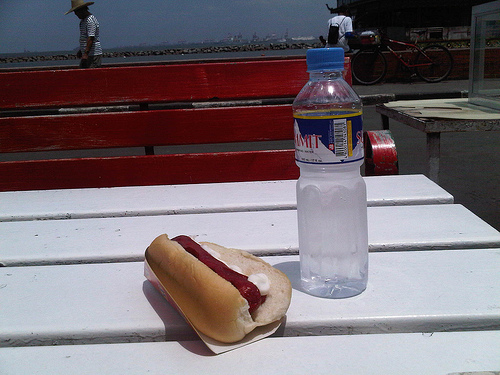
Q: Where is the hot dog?
A: Bun.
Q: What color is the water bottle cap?
A: Blue.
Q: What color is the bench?
A: Red.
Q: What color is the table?
A: White.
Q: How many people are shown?
A: Two.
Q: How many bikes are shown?
A: One.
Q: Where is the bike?
A: At the sidewalk.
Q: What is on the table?
A: Food and water.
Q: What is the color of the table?
A: White.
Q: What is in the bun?
A: A hot dog.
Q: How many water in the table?
A: One.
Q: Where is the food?
A: On the table.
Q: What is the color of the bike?
A: Red.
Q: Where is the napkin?
A: Under the hotdog.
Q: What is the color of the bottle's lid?
A: Blue.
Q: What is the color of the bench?
A: Red.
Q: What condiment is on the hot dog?
A: Mayo.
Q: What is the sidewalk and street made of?
A: Cement and asphalt.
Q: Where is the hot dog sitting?
A: Table.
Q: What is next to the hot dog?
A: Water bottle.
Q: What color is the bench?
A: Red.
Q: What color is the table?
A: White.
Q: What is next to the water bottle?
A: Hot dog.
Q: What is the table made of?
A: Gray wooden slats.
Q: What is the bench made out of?
A: Wood.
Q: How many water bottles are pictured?
A: One.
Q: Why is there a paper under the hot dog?
A: Protection.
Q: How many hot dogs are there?
A: One.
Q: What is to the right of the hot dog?
A: A bottle.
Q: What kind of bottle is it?
A: A water bottle.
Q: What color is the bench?
A: Red.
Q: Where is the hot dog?
A: On the table.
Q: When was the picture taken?
A: Daytime.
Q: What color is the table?
A: White.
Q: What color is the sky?
A: Blue.